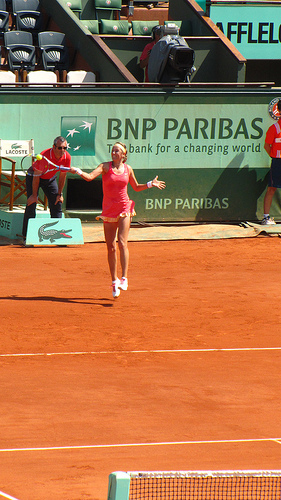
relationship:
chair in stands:
[34, 33, 74, 63] [15, 5, 277, 81]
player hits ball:
[52, 139, 149, 298] [27, 142, 49, 168]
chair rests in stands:
[34, 33, 74, 63] [15, 5, 277, 81]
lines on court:
[9, 339, 280, 454] [13, 241, 280, 492]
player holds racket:
[52, 139, 149, 298] [21, 153, 86, 182]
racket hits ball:
[21, 153, 86, 182] [27, 142, 49, 168]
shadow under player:
[2, 270, 114, 310] [52, 139, 149, 298]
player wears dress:
[52, 139, 149, 298] [100, 141, 126, 224]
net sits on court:
[129, 453, 280, 500] [13, 241, 280, 492]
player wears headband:
[52, 139, 149, 298] [104, 146, 139, 150]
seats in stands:
[77, 1, 203, 33] [1, 1, 275, 89]